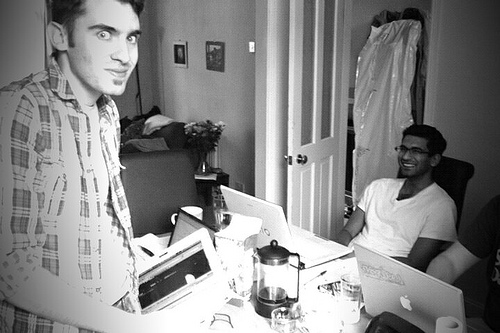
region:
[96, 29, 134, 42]
The man has crazy eyes.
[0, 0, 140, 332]
The man with a crazy look on his face.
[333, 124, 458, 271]
A man in a white shirt and glasses.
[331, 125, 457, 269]
Man is smiling at his friend.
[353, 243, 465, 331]
White apple laptop computer.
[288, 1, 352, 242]
The door is white.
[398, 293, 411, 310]
The apple on a computer.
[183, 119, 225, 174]
A vase of flowers in the background.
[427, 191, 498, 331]
Person in a dark short sleeve shirt.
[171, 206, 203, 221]
White mug hidden behind a computer.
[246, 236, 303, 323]
french press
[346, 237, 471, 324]
apple lap top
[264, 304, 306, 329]
cup sitting on table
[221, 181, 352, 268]
laptop computer sitting on table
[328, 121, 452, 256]
man in white shirt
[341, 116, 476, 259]
man with glasses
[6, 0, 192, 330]
man wearing plaid shirt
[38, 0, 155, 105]
man with eyes wide open looking at camera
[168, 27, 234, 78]
pictures hanging on wall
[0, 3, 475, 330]
group of men sitting around kitchen table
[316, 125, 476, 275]
young man in glasses smiling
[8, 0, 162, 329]
young man wearing a plaid shirt standing and making a silly face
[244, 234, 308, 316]
french press coffee maker on the table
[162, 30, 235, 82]
two framed pictures on the wall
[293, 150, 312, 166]
silver door knob on the white door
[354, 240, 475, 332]
the back of an apple laptop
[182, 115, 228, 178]
a floral bouquet on a small table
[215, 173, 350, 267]
an open laptop on the table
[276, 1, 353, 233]
a white door leading to another room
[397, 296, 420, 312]
apple logo on the back of the laptop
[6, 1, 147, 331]
Man making a funny face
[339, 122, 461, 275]
Man wearing a white t-shirt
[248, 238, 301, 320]
Small lantern sitting on a table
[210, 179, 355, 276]
An open laptop on a table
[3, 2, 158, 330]
Mean wearing a plaid shirt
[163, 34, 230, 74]
Two photographs hanging on a wall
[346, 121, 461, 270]
Man in glasses smiling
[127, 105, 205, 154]
Messy bed in the corner of the room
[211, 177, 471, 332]
Two laptop computers on a table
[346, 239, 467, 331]
Open Apple laptop on a crowded table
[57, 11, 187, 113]
the head of a man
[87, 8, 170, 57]
the eyes of a man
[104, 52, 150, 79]
the nose of a man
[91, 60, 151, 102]
the lips of a man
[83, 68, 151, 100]
the chin of a man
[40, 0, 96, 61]
the ear of a man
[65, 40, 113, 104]
the cheek of a man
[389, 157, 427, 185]
the teeth of a man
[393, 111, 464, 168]
the hair of a man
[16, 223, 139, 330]
the arm of a man